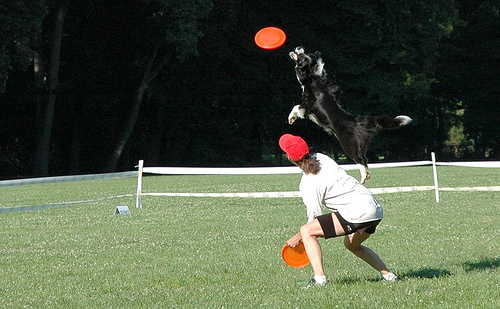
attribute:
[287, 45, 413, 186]
dog — black, jumping, leaping, impressive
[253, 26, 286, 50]
frisbee — orange, red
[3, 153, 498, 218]
fence — white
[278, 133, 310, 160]
cap — red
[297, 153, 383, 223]
thsirt — white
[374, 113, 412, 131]
tail — black, white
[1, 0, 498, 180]
trees — dark, large, tall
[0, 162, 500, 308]
ground — green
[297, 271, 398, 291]
shoes — white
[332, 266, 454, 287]
shadow — long